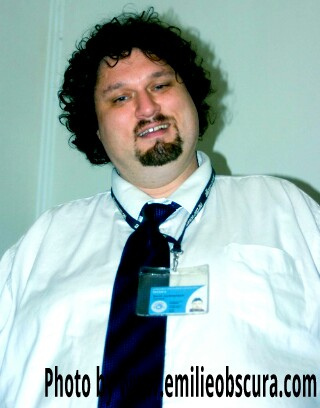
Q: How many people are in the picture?
A: One.